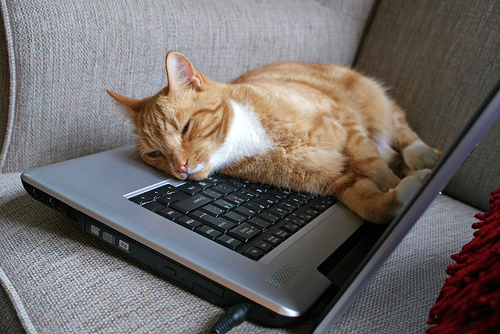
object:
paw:
[402, 142, 437, 170]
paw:
[396, 176, 422, 204]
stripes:
[283, 78, 341, 104]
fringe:
[434, 189, 499, 334]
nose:
[174, 162, 187, 173]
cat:
[106, 50, 442, 225]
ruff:
[210, 97, 273, 182]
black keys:
[169, 193, 211, 214]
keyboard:
[122, 154, 340, 262]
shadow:
[0, 194, 164, 274]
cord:
[204, 302, 251, 333]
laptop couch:
[22, 182, 287, 327]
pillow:
[0, 0, 367, 168]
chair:
[0, 0, 499, 334]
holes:
[32, 188, 44, 201]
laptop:
[18, 84, 499, 334]